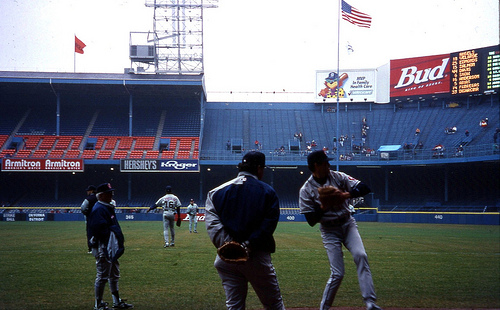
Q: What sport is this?
A: Baseball.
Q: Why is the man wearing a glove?
A: He's playing baseball.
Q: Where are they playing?
A: In a baseball field.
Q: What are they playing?
A: Baseball.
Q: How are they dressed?
A: In baseball uniforms.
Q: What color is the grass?
A: Green.